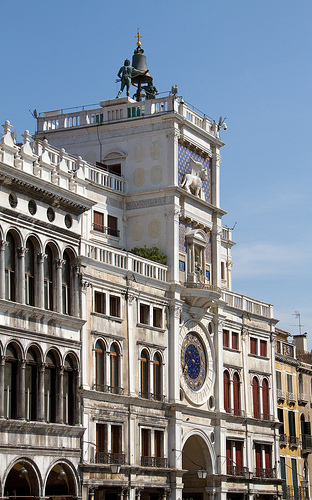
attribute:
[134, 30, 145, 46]
cross — gold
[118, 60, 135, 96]
man — statue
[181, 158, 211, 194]
animal — white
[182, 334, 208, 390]
circle — clock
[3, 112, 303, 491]
building — yellow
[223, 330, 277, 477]
windows — red, arched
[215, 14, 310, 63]
sky — blue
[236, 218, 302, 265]
clouds — white